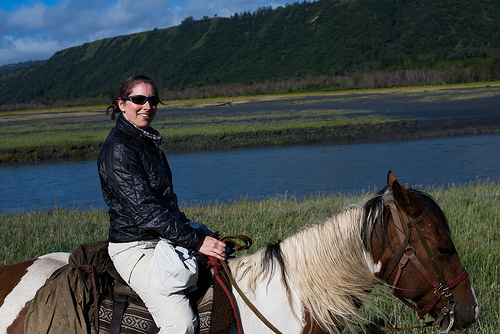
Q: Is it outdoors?
A: Yes, it is outdoors.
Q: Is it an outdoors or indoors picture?
A: It is outdoors.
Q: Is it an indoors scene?
A: No, it is outdoors.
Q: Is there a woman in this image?
A: Yes, there is a woman.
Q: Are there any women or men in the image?
A: Yes, there is a woman.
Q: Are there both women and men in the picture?
A: No, there is a woman but no men.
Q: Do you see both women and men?
A: No, there is a woman but no men.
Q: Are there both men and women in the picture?
A: No, there is a woman but no men.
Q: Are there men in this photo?
A: No, there are no men.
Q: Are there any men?
A: No, there are no men.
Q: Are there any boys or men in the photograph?
A: No, there are no men or boys.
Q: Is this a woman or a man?
A: This is a woman.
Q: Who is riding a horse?
A: The woman is riding a horse.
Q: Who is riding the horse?
A: The woman is riding a horse.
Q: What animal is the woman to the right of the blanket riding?
A: The woman is riding a horse.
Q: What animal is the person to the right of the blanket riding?
A: The woman is riding a horse.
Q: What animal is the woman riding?
A: The woman is riding a horse.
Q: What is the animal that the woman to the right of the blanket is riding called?
A: The animal is a horse.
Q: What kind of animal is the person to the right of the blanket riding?
A: The woman is riding a horse.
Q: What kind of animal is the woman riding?
A: The woman is riding a horse.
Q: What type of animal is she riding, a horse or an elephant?
A: The woman is riding a horse.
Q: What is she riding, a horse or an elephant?
A: The woman is riding a horse.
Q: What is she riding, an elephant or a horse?
A: The woman is riding a horse.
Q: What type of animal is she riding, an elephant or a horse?
A: The woman is riding a horse.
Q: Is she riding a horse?
A: Yes, the woman is riding a horse.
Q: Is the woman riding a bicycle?
A: No, the woman is riding a horse.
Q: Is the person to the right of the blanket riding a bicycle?
A: No, the woman is riding a horse.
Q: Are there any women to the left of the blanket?
A: No, the woman is to the right of the blanket.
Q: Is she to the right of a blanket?
A: Yes, the woman is to the right of a blanket.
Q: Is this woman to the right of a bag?
A: No, the woman is to the right of a blanket.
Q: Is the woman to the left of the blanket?
A: No, the woman is to the right of the blanket.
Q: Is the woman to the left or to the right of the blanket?
A: The woman is to the right of the blanket.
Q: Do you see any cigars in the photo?
A: No, there are no cigars.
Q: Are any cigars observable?
A: No, there are no cigars.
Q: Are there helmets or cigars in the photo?
A: No, there are no cigars or helmets.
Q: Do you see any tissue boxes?
A: No, there are no tissue boxes.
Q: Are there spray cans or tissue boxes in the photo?
A: No, there are no tissue boxes or spray cans.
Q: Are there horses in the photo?
A: Yes, there is a horse.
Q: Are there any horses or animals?
A: Yes, there is a horse.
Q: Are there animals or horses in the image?
A: Yes, there is a horse.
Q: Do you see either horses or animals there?
A: Yes, there is a horse.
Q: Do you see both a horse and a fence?
A: No, there is a horse but no fences.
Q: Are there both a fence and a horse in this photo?
A: No, there is a horse but no fences.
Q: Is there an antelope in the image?
A: No, there are no antelopes.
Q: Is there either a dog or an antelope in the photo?
A: No, there are no antelopes or dogs.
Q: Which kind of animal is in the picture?
A: The animal is a horse.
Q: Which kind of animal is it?
A: The animal is a horse.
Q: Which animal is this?
A: That is a horse.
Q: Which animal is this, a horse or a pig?
A: That is a horse.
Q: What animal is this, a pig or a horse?
A: That is a horse.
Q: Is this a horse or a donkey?
A: This is a horse.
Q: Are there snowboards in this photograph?
A: No, there are no snowboards.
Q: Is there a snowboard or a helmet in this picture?
A: No, there are no snowboards or helmets.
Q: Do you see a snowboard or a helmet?
A: No, there are no snowboards or helmets.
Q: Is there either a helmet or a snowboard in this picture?
A: No, there are no snowboards or helmets.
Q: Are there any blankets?
A: Yes, there is a blanket.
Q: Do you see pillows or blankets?
A: Yes, there is a blanket.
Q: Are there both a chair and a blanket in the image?
A: No, there is a blanket but no chairs.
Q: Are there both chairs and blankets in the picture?
A: No, there is a blanket but no chairs.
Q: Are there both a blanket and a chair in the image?
A: No, there is a blanket but no chairs.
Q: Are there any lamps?
A: No, there are no lamps.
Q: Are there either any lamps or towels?
A: No, there are no lamps or towels.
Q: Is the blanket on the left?
A: Yes, the blanket is on the left of the image.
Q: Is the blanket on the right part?
A: No, the blanket is on the left of the image.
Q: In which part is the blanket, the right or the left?
A: The blanket is on the left of the image.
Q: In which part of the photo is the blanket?
A: The blanket is on the left of the image.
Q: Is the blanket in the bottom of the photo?
A: Yes, the blanket is in the bottom of the image.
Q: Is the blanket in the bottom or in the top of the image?
A: The blanket is in the bottom of the image.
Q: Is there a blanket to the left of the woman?
A: Yes, there is a blanket to the left of the woman.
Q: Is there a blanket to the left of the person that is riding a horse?
A: Yes, there is a blanket to the left of the woman.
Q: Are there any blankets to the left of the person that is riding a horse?
A: Yes, there is a blanket to the left of the woman.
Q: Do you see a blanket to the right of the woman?
A: No, the blanket is to the left of the woman.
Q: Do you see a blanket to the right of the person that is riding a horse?
A: No, the blanket is to the left of the woman.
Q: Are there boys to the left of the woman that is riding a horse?
A: No, there is a blanket to the left of the woman.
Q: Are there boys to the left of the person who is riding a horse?
A: No, there is a blanket to the left of the woman.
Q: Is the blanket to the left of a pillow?
A: No, the blanket is to the left of a woman.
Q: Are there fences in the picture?
A: No, there are no fences.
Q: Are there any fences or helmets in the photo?
A: No, there are no fences or helmets.